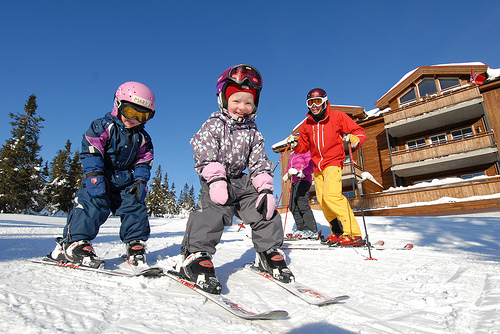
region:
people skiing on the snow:
[43, 55, 393, 292]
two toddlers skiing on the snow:
[35, 58, 291, 314]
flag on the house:
[461, 63, 491, 90]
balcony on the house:
[384, 178, 499, 206]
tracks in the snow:
[65, 289, 135, 326]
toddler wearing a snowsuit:
[28, 69, 168, 279]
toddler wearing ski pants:
[173, 58, 307, 303]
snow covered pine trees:
[150, 164, 190, 216]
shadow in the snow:
[293, 308, 350, 333]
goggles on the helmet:
[225, 62, 266, 88]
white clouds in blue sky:
[18, 12, 71, 50]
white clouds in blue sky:
[53, 17, 101, 49]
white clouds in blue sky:
[40, 56, 77, 96]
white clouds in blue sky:
[128, 13, 173, 54]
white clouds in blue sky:
[168, 21, 197, 56]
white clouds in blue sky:
[228, 16, 273, 45]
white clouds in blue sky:
[276, 7, 304, 56]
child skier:
[65, 83, 159, 276]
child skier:
[172, 57, 286, 279]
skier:
[290, 81, 367, 260]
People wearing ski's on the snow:
[23, 52, 415, 323]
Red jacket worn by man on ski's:
[288, 105, 368, 177]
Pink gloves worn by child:
[193, 162, 280, 224]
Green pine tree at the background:
[1, 89, 53, 214]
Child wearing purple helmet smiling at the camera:
[212, 64, 266, 121]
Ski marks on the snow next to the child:
[355, 261, 497, 332]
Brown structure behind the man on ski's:
[273, 56, 499, 219]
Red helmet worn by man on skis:
[302, 87, 330, 117]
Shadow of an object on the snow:
[368, 213, 498, 263]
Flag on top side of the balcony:
[466, 66, 488, 88]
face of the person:
[214, 71, 276, 136]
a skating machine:
[217, 300, 293, 332]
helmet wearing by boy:
[107, 78, 177, 120]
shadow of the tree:
[401, 200, 494, 252]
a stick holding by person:
[341, 150, 395, 287]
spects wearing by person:
[294, 89, 341, 108]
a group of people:
[57, 55, 425, 312]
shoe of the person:
[173, 246, 243, 291]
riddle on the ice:
[18, 284, 75, 323]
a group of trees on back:
[12, 105, 134, 213]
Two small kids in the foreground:
[41, 45, 356, 330]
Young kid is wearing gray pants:
[172, 158, 293, 263]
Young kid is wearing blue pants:
[47, 163, 169, 265]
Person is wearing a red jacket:
[288, 96, 369, 181]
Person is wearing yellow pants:
[301, 160, 374, 241]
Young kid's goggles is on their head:
[208, 59, 265, 125]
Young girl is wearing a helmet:
[95, 70, 155, 139]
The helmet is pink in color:
[102, 77, 161, 142]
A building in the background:
[270, 55, 497, 220]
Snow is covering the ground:
[3, 209, 495, 331]